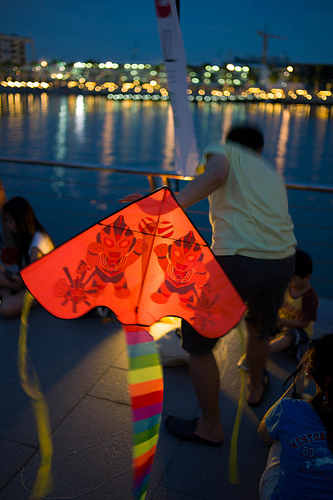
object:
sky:
[0, 0, 332, 63]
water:
[11, 98, 332, 255]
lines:
[17, 289, 165, 498]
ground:
[1, 280, 332, 499]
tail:
[123, 321, 165, 499]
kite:
[18, 183, 249, 498]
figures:
[50, 212, 155, 317]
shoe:
[163, 408, 226, 446]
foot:
[162, 412, 225, 447]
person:
[256, 332, 332, 498]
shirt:
[265, 401, 333, 499]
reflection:
[0, 92, 332, 209]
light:
[120, 315, 183, 346]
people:
[0, 123, 332, 498]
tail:
[16, 290, 56, 498]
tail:
[226, 314, 250, 490]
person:
[122, 116, 298, 447]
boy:
[236, 245, 319, 375]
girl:
[0, 196, 55, 318]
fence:
[0, 153, 332, 318]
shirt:
[206, 136, 298, 262]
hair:
[1, 194, 52, 262]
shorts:
[178, 249, 299, 358]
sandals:
[245, 369, 280, 404]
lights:
[0, 58, 332, 120]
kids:
[238, 247, 332, 498]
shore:
[0, 93, 332, 302]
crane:
[256, 25, 271, 71]